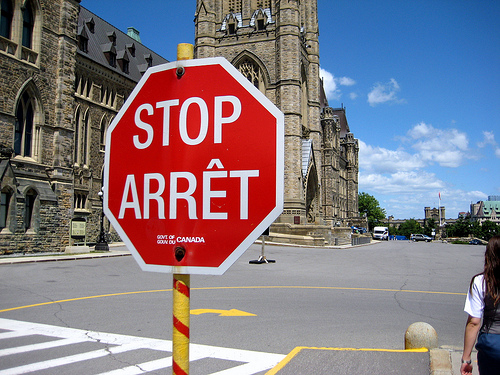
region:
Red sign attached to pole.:
[120, 75, 253, 280]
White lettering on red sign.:
[116, 90, 231, 156]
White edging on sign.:
[92, 60, 317, 310]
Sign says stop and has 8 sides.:
[103, 65, 310, 309]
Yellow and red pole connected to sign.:
[138, 242, 233, 369]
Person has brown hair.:
[473, 239, 498, 269]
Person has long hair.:
[486, 229, 495, 332]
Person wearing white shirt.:
[463, 253, 491, 352]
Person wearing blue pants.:
[471, 327, 490, 369]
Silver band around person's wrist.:
[453, 353, 473, 370]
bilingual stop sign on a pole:
[83, 36, 292, 298]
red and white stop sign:
[95, 43, 290, 288]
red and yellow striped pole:
[164, 275, 193, 374]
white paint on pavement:
[44, 324, 90, 374]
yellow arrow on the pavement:
[194, 297, 260, 333]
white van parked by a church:
[368, 222, 393, 244]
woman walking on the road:
[450, 215, 497, 374]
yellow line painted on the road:
[275, 277, 305, 311]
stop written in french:
[110, 148, 270, 244]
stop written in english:
[114, 68, 251, 163]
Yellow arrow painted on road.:
[192, 289, 267, 341]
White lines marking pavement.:
[23, 298, 101, 372]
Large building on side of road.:
[255, 32, 386, 260]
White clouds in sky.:
[358, 124, 455, 204]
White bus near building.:
[367, 219, 384, 234]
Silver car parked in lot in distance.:
[405, 218, 445, 279]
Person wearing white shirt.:
[462, 275, 490, 315]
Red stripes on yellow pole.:
[153, 272, 218, 364]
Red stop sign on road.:
[108, 80, 262, 278]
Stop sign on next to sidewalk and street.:
[98, 36, 293, 276]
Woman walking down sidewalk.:
[455, 231, 495, 368]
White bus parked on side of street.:
[371, 220, 391, 244]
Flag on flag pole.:
[433, 188, 452, 239]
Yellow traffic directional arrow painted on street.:
[193, 300, 260, 327]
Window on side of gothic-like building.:
[9, 70, 56, 160]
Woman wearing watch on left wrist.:
[457, 356, 478, 369]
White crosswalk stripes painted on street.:
[0, 310, 287, 372]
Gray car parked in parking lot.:
[407, 225, 434, 245]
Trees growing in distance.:
[356, 188, 386, 223]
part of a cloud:
[321, 8, 426, 140]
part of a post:
[168, 305, 204, 347]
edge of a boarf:
[153, 250, 190, 281]